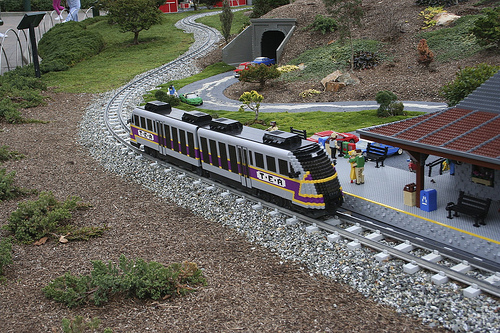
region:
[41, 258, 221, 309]
bush growing in the gravel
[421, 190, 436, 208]
recycle bin on the platform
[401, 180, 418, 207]
trash can on the platform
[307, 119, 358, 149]
red car in the parking lot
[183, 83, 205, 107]
green car on the road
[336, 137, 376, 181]
person waiting on the platform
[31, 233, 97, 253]
yellow leaves on the ground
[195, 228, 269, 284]
brown dirt on the groun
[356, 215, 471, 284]
white train tracks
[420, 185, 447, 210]
blue and white trash can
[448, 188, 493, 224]
black bench in the station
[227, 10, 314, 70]
tunnel at side of the track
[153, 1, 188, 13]
red door on buildings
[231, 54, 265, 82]
red car going into the tunnel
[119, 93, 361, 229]
train on the track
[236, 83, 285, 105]
yellow leaves on tree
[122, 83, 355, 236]
a small model train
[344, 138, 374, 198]
two people on a train platform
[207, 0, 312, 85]
a car tunnel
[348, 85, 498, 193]
a brown overhang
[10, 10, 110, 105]
a large bush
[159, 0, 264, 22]
several red buildings in the background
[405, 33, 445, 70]
a small brown bush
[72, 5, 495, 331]
pebbles underneath the train tracks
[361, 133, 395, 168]
a black bench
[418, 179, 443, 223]
a recycling bin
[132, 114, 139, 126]
window on side of train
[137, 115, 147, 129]
window on side of train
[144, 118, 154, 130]
window on side of train